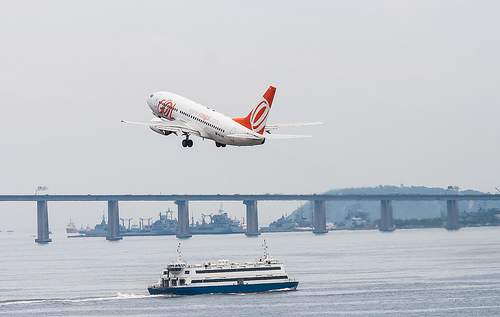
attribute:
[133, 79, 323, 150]
plane — orange, taking off, red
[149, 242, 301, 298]
ship — cruising, white, blue, large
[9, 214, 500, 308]
river — calm, gentle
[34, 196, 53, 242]
column — cement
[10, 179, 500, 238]
bridge — gray, long, dark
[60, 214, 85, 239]
ship — docked, red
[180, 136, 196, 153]
wheel — black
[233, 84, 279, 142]
tail — red, white